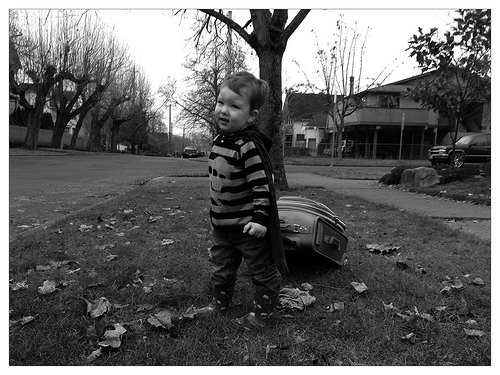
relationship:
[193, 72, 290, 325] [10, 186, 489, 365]
boy standing on grass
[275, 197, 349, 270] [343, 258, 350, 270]
suitcase has wheel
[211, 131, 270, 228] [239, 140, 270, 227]
sweater has sleeve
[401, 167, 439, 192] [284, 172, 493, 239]
boulder next to sidewalk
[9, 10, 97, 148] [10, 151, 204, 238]
tree lining street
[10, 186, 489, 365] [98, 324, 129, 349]
grass has leaf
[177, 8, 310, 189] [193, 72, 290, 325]
tree behind boy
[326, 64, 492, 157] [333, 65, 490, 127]
house has upper deck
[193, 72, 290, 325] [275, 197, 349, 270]
boy pulling suitcase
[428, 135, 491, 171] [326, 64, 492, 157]
suv in front of house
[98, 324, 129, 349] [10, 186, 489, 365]
leaf on top of grass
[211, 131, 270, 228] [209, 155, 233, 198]
sweater has skull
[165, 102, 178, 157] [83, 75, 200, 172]
telephone pole in distance